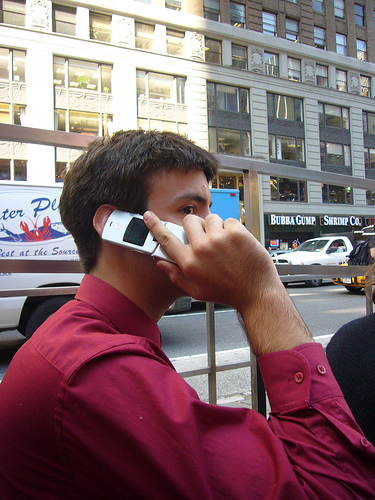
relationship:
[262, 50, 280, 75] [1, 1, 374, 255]
window on building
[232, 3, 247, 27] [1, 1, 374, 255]
window on building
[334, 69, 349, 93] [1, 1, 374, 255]
window on building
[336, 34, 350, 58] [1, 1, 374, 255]
window on building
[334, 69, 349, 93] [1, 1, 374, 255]
window in building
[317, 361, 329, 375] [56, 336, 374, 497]
button on shirt sleeve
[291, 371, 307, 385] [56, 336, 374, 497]
button on shirt sleeve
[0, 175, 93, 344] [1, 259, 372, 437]
truck on road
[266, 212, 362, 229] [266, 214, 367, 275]
lettering on store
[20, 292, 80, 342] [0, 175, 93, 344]
tire on truck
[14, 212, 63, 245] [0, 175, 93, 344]
lobster printed on truck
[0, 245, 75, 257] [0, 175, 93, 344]
lettering on truck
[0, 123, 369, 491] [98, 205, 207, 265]
man on phone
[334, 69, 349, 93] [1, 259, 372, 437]
window over a road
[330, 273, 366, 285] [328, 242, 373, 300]
bumper on car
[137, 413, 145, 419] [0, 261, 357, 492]
speck of dirt on shirt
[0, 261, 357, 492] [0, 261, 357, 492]
man wearing shirt